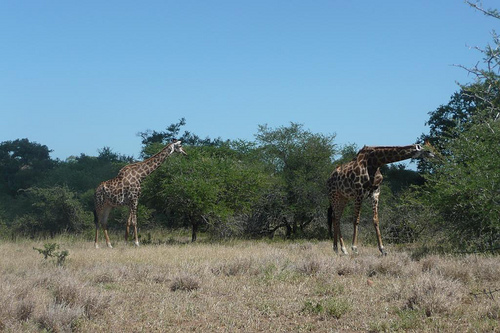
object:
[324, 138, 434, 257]
giraffe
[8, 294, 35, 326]
grass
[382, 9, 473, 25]
sky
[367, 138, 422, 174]
neck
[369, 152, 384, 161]
shadow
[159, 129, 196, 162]
head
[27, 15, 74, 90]
sky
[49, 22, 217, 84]
clouds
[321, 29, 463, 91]
clouds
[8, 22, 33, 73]
sky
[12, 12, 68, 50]
clouds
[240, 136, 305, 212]
leaves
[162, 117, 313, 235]
tree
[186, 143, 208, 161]
leaves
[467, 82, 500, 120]
leaves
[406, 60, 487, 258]
tree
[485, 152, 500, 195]
leaves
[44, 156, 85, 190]
leaves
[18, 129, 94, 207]
tree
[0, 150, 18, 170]
leaves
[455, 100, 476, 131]
leaves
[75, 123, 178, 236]
giraffe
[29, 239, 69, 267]
bush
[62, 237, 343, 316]
field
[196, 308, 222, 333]
grass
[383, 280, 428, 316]
grass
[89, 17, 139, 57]
sky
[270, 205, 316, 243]
trunks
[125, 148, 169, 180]
neck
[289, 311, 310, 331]
grass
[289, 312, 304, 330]
grass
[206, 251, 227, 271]
grass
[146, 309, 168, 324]
grass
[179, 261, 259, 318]
grass